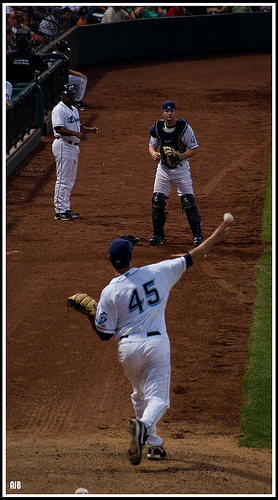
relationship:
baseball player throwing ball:
[66, 217, 232, 467] [223, 211, 234, 225]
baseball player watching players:
[51, 83, 99, 223] [82, 94, 236, 471]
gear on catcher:
[142, 120, 197, 162] [132, 87, 215, 247]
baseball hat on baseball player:
[107, 238, 134, 264] [66, 217, 232, 467]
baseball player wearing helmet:
[51, 83, 99, 223] [62, 83, 76, 96]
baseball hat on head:
[109, 238, 134, 264] [106, 239, 133, 275]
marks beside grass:
[195, 127, 271, 210] [246, 142, 269, 454]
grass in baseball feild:
[246, 142, 269, 454] [6, 40, 269, 490]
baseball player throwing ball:
[66, 217, 232, 467] [223, 211, 233, 222]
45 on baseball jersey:
[128, 278, 161, 315] [95, 256, 187, 341]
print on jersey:
[127, 278, 160, 318] [92, 254, 192, 334]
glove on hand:
[61, 286, 99, 324] [211, 214, 247, 258]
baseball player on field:
[51, 83, 99, 223] [5, 4, 273, 494]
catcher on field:
[149, 100, 204, 249] [5, 4, 273, 494]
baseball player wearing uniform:
[66, 217, 232, 467] [92, 252, 194, 448]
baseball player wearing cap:
[66, 217, 232, 467] [102, 226, 146, 272]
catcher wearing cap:
[149, 100, 204, 249] [157, 96, 189, 122]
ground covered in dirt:
[25, 341, 106, 494] [187, 313, 243, 496]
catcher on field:
[148, 100, 205, 244] [6, 52, 270, 497]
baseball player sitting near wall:
[51, 83, 99, 223] [62, 19, 230, 94]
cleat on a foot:
[126, 417, 146, 466] [125, 418, 146, 466]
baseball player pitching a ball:
[66, 217, 232, 467] [220, 210, 241, 231]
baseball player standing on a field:
[47, 81, 102, 221] [6, 52, 270, 497]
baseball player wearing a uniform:
[51, 83, 99, 223] [50, 101, 81, 212]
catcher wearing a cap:
[149, 100, 204, 249] [162, 99, 176, 109]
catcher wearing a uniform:
[149, 100, 204, 249] [146, 116, 204, 237]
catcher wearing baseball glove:
[149, 100, 204, 249] [159, 142, 180, 169]